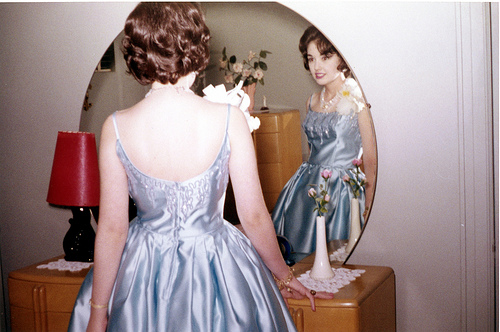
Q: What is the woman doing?
A: Looking in the mirror.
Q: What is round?
A: Mirror.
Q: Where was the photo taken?
A: In a room.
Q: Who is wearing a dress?
A: Woman.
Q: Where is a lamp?
A: On the dresser.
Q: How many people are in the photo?
A: One.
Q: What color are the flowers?
A: Pink.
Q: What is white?
A: Flower vase.